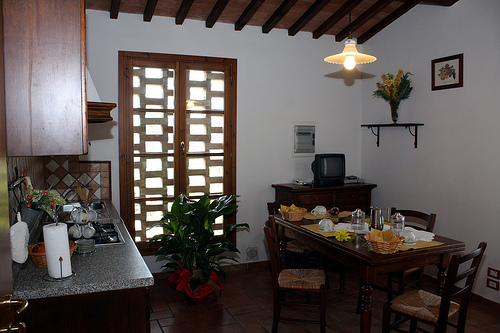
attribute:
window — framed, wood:
[123, 58, 230, 248]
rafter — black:
[310, 3, 357, 38]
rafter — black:
[261, 2, 293, 36]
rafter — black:
[204, 2, 228, 30]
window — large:
[113, 43, 246, 260]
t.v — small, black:
[307, 144, 358, 196]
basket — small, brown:
[365, 227, 407, 255]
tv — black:
[311, 151, 346, 189]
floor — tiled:
[166, 255, 346, 327]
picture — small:
[427, 53, 466, 93]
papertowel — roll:
[38, 219, 73, 279]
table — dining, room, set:
[263, 210, 467, 331]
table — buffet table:
[273, 187, 478, 292]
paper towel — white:
[43, 225, 73, 262]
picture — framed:
[431, 52, 464, 89]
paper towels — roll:
[41, 217, 75, 285]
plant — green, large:
[150, 185, 246, 306]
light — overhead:
[291, 19, 388, 104]